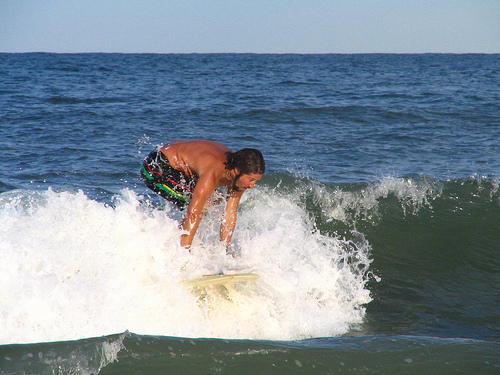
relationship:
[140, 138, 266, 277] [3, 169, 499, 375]
man on wave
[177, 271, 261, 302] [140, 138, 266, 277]
surfboard under man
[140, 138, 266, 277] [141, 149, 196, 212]
man has trunks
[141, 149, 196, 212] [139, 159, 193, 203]
trunks have stripes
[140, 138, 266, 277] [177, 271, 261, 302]
man over surfboard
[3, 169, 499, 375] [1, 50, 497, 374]
wave in ocean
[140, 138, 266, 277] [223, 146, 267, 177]
man has hair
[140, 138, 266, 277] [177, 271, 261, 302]
man riding surfboard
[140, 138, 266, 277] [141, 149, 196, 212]
man wearing trunks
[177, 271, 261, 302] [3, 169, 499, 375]
surfboard in wave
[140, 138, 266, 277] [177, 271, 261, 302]
man on surfboard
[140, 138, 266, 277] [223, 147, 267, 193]
man has head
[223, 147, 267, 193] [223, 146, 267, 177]
head has hair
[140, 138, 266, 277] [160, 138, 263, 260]
man has skin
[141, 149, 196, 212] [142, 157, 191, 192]
trunks has stripe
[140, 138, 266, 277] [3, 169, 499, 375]
man in wave